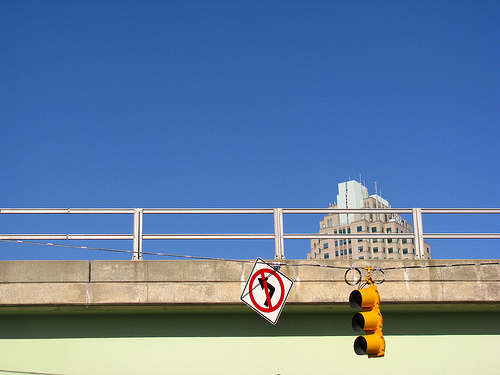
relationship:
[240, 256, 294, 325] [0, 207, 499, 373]
sign hanging near bridge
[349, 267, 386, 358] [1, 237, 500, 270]
traffic light hanging from wire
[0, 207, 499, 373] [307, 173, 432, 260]
bridge in front of building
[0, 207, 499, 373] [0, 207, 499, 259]
bridge has a railing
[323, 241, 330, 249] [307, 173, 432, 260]
window on building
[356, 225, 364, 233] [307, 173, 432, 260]
window on building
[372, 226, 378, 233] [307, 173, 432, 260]
window on building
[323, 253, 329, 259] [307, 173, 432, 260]
window on building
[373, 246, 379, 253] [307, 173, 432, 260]
window on building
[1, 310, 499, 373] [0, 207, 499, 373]
shadow cast on bridge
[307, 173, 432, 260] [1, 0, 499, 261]
building under sky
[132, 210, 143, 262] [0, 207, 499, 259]
post on railing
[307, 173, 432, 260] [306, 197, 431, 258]
building has lot of windows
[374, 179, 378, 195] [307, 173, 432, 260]
pole on building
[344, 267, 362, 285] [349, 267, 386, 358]
wire near traffic light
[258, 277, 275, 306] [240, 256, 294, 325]
arrow on sign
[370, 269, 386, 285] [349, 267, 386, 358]
wire behind traffic light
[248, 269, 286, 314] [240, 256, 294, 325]
circle on sign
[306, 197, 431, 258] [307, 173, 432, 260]
lot of windows on building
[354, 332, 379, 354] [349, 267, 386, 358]
bottom of traffic light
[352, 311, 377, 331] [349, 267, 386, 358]
middle of traffic light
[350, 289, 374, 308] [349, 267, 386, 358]
top of traffic light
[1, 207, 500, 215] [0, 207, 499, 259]
horizontal bar on railing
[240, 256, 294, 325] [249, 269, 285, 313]
sign says no left turn